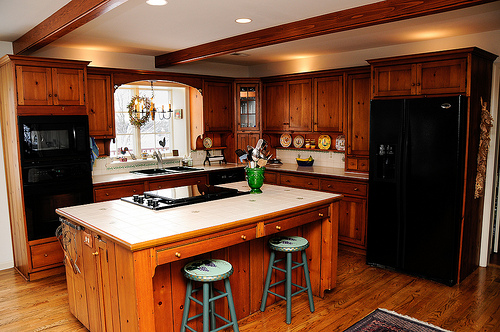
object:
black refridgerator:
[363, 92, 467, 288]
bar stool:
[179, 256, 238, 332]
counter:
[56, 179, 340, 249]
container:
[245, 167, 267, 194]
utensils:
[235, 137, 273, 167]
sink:
[135, 166, 199, 174]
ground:
[397, 284, 435, 324]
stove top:
[121, 182, 249, 210]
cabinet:
[10, 58, 83, 108]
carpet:
[334, 304, 459, 332]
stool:
[263, 234, 315, 323]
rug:
[337, 305, 455, 332]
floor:
[2, 236, 498, 328]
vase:
[246, 167, 265, 194]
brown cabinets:
[268, 65, 373, 252]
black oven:
[18, 111, 93, 241]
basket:
[296, 158, 313, 167]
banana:
[297, 155, 311, 161]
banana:
[306, 154, 313, 161]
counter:
[250, 160, 367, 180]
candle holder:
[132, 80, 174, 121]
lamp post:
[170, 206, 221, 231]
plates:
[335, 134, 346, 151]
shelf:
[274, 132, 347, 169]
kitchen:
[0, 0, 499, 332]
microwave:
[19, 110, 95, 162]